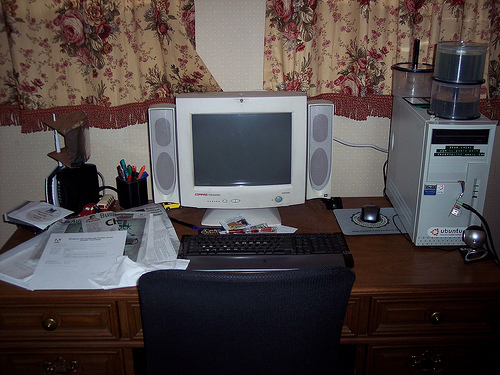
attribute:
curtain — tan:
[260, 0, 496, 105]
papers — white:
[2, 207, 187, 307]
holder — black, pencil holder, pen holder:
[116, 170, 148, 207]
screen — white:
[175, 92, 307, 207]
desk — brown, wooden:
[4, 247, 498, 357]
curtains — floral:
[2, 2, 499, 142]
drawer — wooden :
[2, 297, 127, 349]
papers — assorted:
[3, 199, 302, 288]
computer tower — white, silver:
[378, 83, 498, 255]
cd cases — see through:
[389, 30, 489, 123]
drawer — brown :
[3, 300, 116, 336]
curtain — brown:
[6, 18, 169, 110]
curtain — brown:
[265, 15, 382, 82]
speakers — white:
[136, 107, 231, 218]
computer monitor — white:
[172, 90, 307, 212]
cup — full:
[111, 170, 149, 206]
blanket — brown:
[1, 3, 224, 129]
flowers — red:
[3, 3, 491, 115]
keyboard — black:
[175, 229, 353, 269]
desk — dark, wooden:
[1, 196, 499, 372]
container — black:
[110, 168, 158, 219]